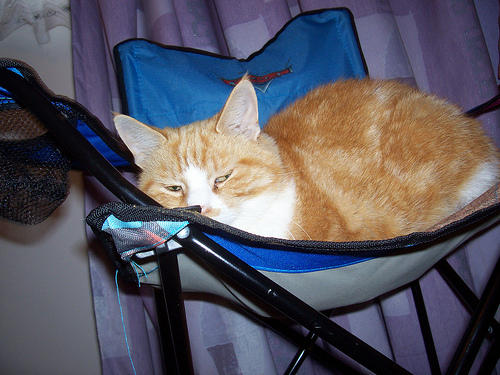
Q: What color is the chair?
A: Blue.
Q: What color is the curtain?
A: Purple.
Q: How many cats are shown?
A: One.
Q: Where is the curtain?
A: Behind chair.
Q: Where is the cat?
A: On chair.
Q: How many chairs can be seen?
A: One.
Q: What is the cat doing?
A: Laying.